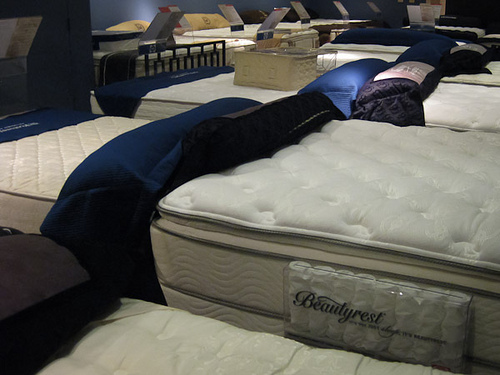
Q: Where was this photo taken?
A: In a mattress store.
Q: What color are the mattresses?
A: White.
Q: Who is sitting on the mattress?
A: No one.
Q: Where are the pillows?
A: On top of the mattresses.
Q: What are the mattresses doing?
A: Nothing.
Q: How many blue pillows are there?
A: Four.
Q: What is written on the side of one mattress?
A: Beautyrest.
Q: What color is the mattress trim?
A: Brown.